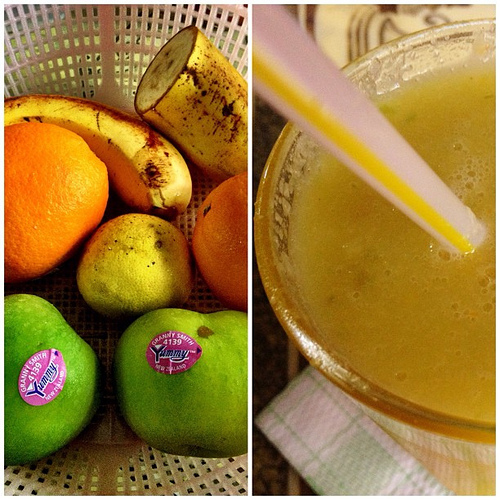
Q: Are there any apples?
A: Yes, there is an apple.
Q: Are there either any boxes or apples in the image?
A: Yes, there is an apple.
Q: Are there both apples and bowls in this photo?
A: No, there is an apple but no bowls.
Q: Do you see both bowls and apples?
A: No, there is an apple but no bowls.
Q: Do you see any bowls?
A: No, there are no bowls.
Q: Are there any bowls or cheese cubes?
A: No, there are no bowls or cheese cubes.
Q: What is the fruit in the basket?
A: The fruit is an apple.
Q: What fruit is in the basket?
A: The fruit is an apple.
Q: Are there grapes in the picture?
A: No, there are no grapes.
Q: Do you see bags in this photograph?
A: No, there are no bags.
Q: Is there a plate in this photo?
A: No, there are no plates.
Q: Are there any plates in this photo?
A: No, there are no plates.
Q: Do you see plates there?
A: No, there are no plates.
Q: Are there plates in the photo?
A: No, there are no plates.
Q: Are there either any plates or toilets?
A: No, there are no plates or toilets.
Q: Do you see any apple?
A: Yes, there is an apple.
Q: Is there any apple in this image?
A: Yes, there is an apple.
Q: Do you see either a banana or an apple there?
A: Yes, there is an apple.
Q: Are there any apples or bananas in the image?
A: Yes, there is an apple.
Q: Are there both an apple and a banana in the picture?
A: Yes, there are both an apple and a banana.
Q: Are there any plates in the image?
A: No, there are no plates.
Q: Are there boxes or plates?
A: No, there are no plates or boxes.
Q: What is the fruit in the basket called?
A: The fruit is an apple.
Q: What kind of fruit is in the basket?
A: The fruit is an apple.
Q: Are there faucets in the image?
A: No, there are no faucets.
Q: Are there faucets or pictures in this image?
A: No, there are no faucets or pictures.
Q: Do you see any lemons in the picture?
A: Yes, there is a lemon.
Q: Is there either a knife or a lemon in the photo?
A: Yes, there is a lemon.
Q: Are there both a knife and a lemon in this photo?
A: No, there is a lemon but no knives.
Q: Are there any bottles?
A: No, there are no bottles.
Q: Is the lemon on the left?
A: Yes, the lemon is on the left of the image.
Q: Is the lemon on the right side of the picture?
A: No, the lemon is on the left of the image.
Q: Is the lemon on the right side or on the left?
A: The lemon is on the left of the image.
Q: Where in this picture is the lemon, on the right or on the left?
A: The lemon is on the left of the image.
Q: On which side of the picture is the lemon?
A: The lemon is on the left of the image.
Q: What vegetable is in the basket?
A: The vegetable is a lemon.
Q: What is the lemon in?
A: The lemon is in the basket.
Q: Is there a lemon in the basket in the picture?
A: Yes, there is a lemon in the basket.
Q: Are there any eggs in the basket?
A: No, there is a lemon in the basket.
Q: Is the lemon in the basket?
A: Yes, the lemon is in the basket.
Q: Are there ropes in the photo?
A: No, there are no ropes.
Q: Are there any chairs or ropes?
A: No, there are no ropes or chairs.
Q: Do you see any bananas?
A: Yes, there is a banana.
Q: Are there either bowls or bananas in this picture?
A: Yes, there is a banana.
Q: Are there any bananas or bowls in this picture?
A: Yes, there is a banana.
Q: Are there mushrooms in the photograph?
A: No, there are no mushrooms.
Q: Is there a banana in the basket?
A: Yes, there is a banana in the basket.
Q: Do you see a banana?
A: Yes, there is a banana.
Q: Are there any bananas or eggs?
A: Yes, there is a banana.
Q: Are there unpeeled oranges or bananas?
A: Yes, there is an unpeeled banana.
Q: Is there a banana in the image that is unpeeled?
A: Yes, there is an unpeeled banana.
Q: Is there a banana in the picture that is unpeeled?
A: Yes, there is a banana that is unpeeled.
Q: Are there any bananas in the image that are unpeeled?
A: Yes, there is a banana that is unpeeled.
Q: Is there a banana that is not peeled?
A: Yes, there is a unpeeled banana.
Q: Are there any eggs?
A: No, there are no eggs.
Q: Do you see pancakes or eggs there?
A: No, there are no eggs or pancakes.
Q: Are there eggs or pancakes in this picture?
A: No, there are no eggs or pancakes.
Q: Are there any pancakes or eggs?
A: No, there are no eggs or pancakes.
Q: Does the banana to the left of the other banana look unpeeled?
A: Yes, the banana is unpeeled.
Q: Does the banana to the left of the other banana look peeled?
A: No, the banana is unpeeled.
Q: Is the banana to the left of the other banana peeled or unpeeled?
A: The banana is unpeeled.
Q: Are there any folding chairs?
A: No, there are no folding chairs.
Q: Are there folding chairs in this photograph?
A: No, there are no folding chairs.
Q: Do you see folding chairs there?
A: No, there are no folding chairs.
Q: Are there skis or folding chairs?
A: No, there are no folding chairs or skis.